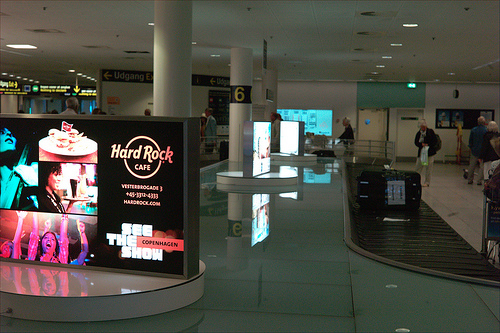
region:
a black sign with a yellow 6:
[225, 81, 254, 106]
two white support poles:
[148, 0, 255, 190]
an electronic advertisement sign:
[0, 113, 202, 282]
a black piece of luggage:
[350, 164, 425, 220]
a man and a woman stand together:
[462, 113, 498, 188]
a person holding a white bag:
[409, 120, 441, 194]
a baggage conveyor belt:
[340, 151, 497, 287]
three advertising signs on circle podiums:
[1, 103, 318, 325]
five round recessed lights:
[361, 17, 420, 86]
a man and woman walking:
[195, 103, 220, 154]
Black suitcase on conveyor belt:
[354, 166, 423, 219]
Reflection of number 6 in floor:
[227, 217, 247, 239]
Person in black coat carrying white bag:
[412, 117, 442, 187]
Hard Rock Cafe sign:
[107, 130, 174, 207]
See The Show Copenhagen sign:
[105, 222, 184, 261]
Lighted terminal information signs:
[0, 76, 96, 99]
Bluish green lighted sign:
[277, 107, 334, 136]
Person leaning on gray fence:
[338, 114, 356, 156]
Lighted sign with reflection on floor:
[251, 117, 273, 247]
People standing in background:
[196, 107, 218, 159]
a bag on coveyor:
[348, 152, 435, 229]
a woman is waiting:
[411, 104, 440, 197]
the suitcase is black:
[341, 152, 433, 224]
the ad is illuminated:
[13, 99, 185, 280]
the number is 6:
[224, 79, 271, 116]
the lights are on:
[372, 15, 427, 138]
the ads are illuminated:
[224, 106, 311, 218]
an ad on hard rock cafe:
[108, 121, 183, 222]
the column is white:
[215, 46, 259, 196]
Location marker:
[226, 83, 253, 103]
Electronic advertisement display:
[2, 113, 194, 277]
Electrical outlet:
[2, 301, 18, 317]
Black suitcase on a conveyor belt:
[354, 166, 423, 218]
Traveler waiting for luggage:
[409, 117, 439, 189]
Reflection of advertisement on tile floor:
[251, 190, 272, 245]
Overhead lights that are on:
[358, 20, 418, 83]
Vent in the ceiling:
[23, 22, 65, 39]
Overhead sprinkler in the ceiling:
[112, 31, 122, 38]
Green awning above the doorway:
[353, 81, 428, 109]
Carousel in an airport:
[200, 128, 499, 283]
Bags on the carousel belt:
[220, 135, 424, 207]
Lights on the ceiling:
[5, 22, 456, 81]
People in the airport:
[336, 112, 496, 187]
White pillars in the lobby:
[153, 1, 254, 181]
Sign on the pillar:
[227, 84, 252, 104]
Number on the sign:
[233, 84, 245, 101]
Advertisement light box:
[0, 116, 197, 278]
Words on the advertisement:
[107, 143, 184, 260]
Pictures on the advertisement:
[2, 121, 100, 263]